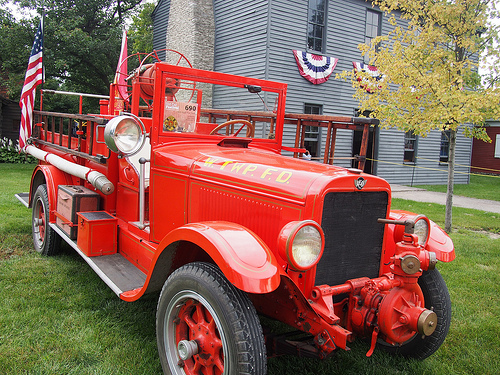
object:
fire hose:
[24, 144, 115, 195]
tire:
[375, 266, 451, 362]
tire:
[156, 261, 269, 375]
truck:
[27, 49, 455, 375]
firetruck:
[15, 49, 455, 374]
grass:
[1, 175, 498, 372]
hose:
[129, 62, 190, 96]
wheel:
[31, 182, 57, 249]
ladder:
[32, 110, 109, 164]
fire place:
[162, 0, 212, 132]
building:
[151, 0, 484, 185]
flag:
[18, 18, 45, 154]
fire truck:
[14, 48, 455, 374]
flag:
[108, 30, 129, 115]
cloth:
[292, 49, 338, 84]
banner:
[293, 49, 339, 84]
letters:
[204, 157, 293, 183]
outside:
[4, 5, 498, 371]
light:
[414, 217, 430, 247]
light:
[292, 223, 324, 267]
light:
[104, 112, 146, 157]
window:
[303, 0, 450, 167]